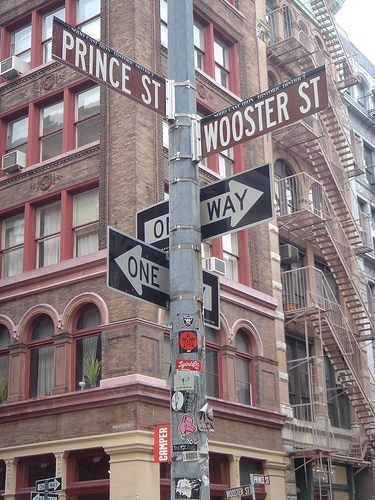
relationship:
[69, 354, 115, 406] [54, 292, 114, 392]
plant on window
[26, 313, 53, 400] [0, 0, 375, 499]
window on building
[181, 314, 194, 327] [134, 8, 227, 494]
sticker on pole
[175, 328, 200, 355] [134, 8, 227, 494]
sticker on pole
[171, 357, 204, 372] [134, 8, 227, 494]
sticker on pole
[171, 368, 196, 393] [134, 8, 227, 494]
sticker on pole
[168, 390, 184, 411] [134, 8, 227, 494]
sticker on pole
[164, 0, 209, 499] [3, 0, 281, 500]
pole near building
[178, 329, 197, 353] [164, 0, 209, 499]
sticker on pole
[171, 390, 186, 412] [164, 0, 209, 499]
sticker on pole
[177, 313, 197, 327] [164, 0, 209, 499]
sticker on pole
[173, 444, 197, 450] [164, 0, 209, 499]
sticker on pole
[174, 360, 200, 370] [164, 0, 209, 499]
sticker on pole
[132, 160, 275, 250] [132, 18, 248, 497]
sign on pole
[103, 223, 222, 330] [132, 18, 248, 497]
sign on pole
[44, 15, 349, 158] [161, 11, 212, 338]
signs on pole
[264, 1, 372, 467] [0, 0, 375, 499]
steps attached to building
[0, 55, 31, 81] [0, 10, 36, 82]
air conditioner attached to window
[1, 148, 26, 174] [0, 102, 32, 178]
ac attached to window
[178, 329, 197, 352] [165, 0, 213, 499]
sticker on pole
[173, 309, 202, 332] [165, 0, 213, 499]
sticker on pole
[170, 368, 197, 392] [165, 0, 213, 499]
sticker on pole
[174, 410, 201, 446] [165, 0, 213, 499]
sticker on pole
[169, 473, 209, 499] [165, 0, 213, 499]
sticker on pole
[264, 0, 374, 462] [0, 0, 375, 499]
ladder on building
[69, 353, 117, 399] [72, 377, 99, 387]
plant in window sill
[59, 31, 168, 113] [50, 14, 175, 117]
prince st on sign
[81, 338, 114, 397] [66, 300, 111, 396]
plant in window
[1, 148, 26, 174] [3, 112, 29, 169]
ac in window